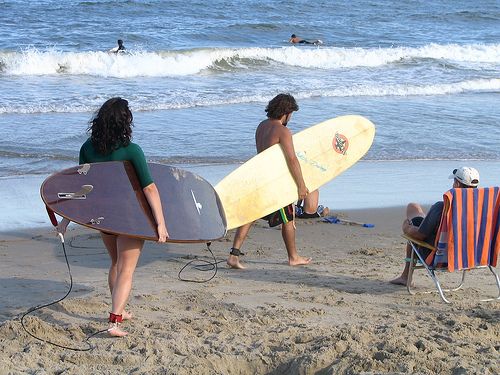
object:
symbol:
[332, 131, 349, 158]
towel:
[446, 187, 498, 271]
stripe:
[462, 188, 467, 269]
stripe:
[467, 188, 475, 268]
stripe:
[480, 187, 493, 266]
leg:
[108, 235, 145, 325]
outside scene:
[0, 0, 500, 373]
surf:
[154, 52, 218, 91]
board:
[39, 160, 228, 243]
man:
[388, 166, 480, 287]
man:
[226, 92, 313, 270]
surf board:
[213, 114, 376, 230]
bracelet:
[20, 205, 117, 351]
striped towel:
[425, 186, 500, 270]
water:
[0, 0, 500, 162]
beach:
[0, 123, 500, 375]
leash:
[21, 200, 124, 352]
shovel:
[323, 216, 375, 228]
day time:
[0, 0, 500, 374]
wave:
[0, 42, 500, 80]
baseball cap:
[448, 167, 481, 188]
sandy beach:
[0, 166, 497, 375]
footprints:
[0, 290, 500, 375]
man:
[288, 33, 322, 46]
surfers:
[78, 96, 170, 337]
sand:
[1, 232, 500, 374]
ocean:
[0, 14, 500, 161]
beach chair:
[398, 186, 498, 306]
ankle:
[106, 317, 121, 327]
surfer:
[108, 39, 129, 53]